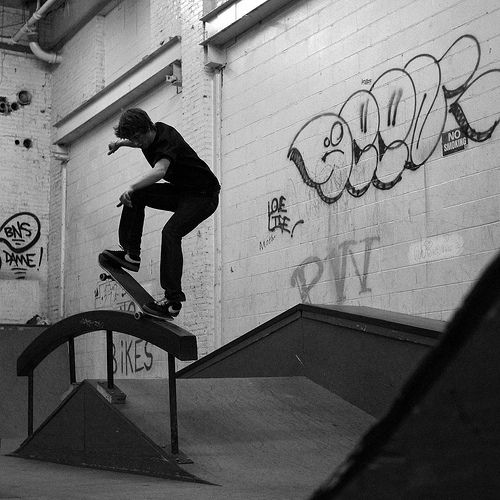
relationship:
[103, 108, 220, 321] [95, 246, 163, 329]
boy on board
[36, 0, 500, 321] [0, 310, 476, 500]
wall near ramp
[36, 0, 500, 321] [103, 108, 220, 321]
wall behind boy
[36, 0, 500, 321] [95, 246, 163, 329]
wall behind board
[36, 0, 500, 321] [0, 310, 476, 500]
wall behind ramp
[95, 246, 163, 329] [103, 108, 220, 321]
board under boy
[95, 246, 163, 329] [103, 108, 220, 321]
board below boy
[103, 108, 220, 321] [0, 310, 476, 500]
boy on ramp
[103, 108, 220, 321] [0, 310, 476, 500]
boy above ramp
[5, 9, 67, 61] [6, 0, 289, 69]
pipes on ceiling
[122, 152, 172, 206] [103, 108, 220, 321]
arm of boy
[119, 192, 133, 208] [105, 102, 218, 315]
hand of person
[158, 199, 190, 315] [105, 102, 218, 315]
leg of person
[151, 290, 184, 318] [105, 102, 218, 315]
shoe on person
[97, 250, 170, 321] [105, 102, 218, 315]
skateboard under person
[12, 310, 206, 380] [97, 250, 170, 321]
railing under skateboard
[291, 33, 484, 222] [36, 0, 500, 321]
graffiti on wall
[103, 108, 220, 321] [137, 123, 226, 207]
boy has shirt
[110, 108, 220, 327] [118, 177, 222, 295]
boy has pants